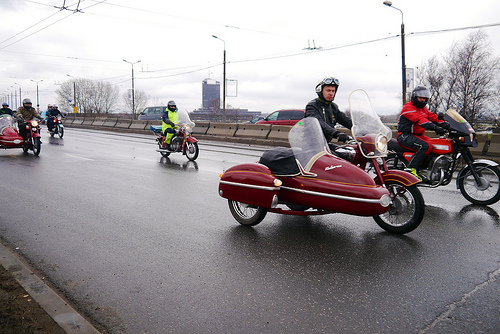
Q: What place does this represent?
A: It represents the street.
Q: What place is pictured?
A: It is a street.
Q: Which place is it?
A: It is a street.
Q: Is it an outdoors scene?
A: Yes, it is outdoors.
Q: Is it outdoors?
A: Yes, it is outdoors.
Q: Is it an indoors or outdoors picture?
A: It is outdoors.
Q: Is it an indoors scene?
A: No, it is outdoors.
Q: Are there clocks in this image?
A: No, there are no clocks.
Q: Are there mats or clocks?
A: No, there are no clocks or mats.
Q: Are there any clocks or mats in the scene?
A: No, there are no clocks or mats.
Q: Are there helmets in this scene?
A: Yes, there is a helmet.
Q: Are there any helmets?
A: Yes, there is a helmet.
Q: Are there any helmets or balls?
A: Yes, there is a helmet.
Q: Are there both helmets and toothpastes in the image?
A: No, there is a helmet but no toothpastes.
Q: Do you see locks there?
A: No, there are no locks.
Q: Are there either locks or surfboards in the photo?
A: No, there are no locks or surfboards.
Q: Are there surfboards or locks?
A: No, there are no locks or surfboards.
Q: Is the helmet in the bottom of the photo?
A: No, the helmet is in the top of the image.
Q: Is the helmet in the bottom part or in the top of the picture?
A: The helmet is in the top of the image.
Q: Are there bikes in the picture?
A: Yes, there is a bike.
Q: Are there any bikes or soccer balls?
A: Yes, there is a bike.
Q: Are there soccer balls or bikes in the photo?
A: Yes, there is a bike.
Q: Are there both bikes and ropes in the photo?
A: No, there is a bike but no ropes.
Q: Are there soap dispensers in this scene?
A: No, there are no soap dispensers.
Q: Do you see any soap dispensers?
A: No, there are no soap dispensers.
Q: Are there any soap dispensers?
A: No, there are no soap dispensers.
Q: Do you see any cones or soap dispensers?
A: No, there are no soap dispensers or cones.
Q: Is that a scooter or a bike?
A: That is a bike.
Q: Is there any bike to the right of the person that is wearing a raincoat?
A: Yes, there is a bike to the right of the person.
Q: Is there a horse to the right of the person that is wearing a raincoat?
A: No, there is a bike to the right of the person.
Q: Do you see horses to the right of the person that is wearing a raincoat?
A: No, there is a bike to the right of the person.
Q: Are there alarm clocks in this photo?
A: No, there are no alarm clocks.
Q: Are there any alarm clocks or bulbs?
A: No, there are no alarm clocks or bulbs.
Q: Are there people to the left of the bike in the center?
A: Yes, there is a person to the left of the bike.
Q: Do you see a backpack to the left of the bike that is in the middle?
A: No, there is a person to the left of the bike.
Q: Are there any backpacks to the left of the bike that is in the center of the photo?
A: No, there is a person to the left of the bike.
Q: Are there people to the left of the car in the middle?
A: Yes, there is a person to the left of the car.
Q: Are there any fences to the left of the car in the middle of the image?
A: No, there is a person to the left of the car.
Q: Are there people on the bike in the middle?
A: Yes, there is a person on the bike.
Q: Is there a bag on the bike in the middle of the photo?
A: No, there is a person on the bike.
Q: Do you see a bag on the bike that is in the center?
A: No, there is a person on the bike.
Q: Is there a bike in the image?
A: Yes, there is a bike.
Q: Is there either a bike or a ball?
A: Yes, there is a bike.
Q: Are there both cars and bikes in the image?
A: Yes, there are both a bike and a car.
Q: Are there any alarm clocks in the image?
A: No, there are no alarm clocks.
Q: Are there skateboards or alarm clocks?
A: No, there are no alarm clocks or skateboards.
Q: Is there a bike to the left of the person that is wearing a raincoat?
A: Yes, there is a bike to the left of the person.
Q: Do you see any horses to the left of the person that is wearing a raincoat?
A: No, there is a bike to the left of the person.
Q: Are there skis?
A: No, there are no skis.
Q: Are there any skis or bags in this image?
A: No, there are no skis or bags.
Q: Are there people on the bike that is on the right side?
A: Yes, there is a person on the bike.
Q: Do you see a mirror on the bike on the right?
A: No, there is a person on the bike.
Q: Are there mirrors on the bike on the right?
A: No, there is a person on the bike.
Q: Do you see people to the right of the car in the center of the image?
A: Yes, there is a person to the right of the car.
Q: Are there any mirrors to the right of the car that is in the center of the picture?
A: No, there is a person to the right of the car.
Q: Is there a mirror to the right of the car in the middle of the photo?
A: No, there is a person to the right of the car.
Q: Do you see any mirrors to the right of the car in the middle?
A: No, there is a person to the right of the car.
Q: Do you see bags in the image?
A: No, there are no bags.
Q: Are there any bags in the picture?
A: No, there are no bags.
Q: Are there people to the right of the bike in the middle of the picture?
A: Yes, there is a person to the right of the bike.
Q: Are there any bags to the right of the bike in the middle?
A: No, there is a person to the right of the bike.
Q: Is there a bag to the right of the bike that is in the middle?
A: No, there is a person to the right of the bike.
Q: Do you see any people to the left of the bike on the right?
A: Yes, there is a person to the left of the bike.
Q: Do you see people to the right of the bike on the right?
A: No, the person is to the left of the bike.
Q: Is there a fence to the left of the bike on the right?
A: No, there is a person to the left of the bike.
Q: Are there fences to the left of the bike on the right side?
A: No, there is a person to the left of the bike.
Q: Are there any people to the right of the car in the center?
A: Yes, there is a person to the right of the car.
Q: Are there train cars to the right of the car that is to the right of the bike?
A: No, there is a person to the right of the car.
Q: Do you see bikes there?
A: Yes, there are bikes.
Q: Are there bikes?
A: Yes, there are bikes.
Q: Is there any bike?
A: Yes, there are bikes.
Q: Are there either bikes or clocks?
A: Yes, there are bikes.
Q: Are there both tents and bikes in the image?
A: No, there are bikes but no tents.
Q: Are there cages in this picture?
A: No, there are no cages.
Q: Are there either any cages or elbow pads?
A: No, there are no cages or elbow pads.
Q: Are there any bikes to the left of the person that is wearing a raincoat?
A: Yes, there are bikes to the left of the person.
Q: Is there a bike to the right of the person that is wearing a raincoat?
A: No, the bikes are to the left of the person.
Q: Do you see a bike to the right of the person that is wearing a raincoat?
A: No, the bikes are to the left of the person.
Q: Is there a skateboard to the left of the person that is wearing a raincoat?
A: No, there are bikes to the left of the person.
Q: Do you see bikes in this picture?
A: Yes, there is a bike.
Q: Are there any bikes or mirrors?
A: Yes, there is a bike.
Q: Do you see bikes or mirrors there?
A: Yes, there is a bike.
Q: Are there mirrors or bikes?
A: Yes, there is a bike.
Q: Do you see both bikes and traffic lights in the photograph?
A: No, there is a bike but no traffic lights.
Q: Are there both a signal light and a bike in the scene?
A: No, there is a bike but no traffic lights.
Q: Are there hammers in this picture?
A: No, there are no hammers.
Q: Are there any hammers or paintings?
A: No, there are no hammers or paintings.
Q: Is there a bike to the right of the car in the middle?
A: Yes, there is a bike to the right of the car.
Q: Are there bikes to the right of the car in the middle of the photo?
A: Yes, there is a bike to the right of the car.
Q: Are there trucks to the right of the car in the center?
A: No, there is a bike to the right of the car.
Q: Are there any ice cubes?
A: No, there are no ice cubes.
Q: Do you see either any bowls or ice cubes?
A: No, there are no ice cubes or bowls.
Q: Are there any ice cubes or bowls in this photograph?
A: No, there are no ice cubes or bowls.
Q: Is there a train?
A: No, there are no trains.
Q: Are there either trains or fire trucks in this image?
A: No, there are no trains or fire trucks.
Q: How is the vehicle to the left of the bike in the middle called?
A: The vehicle is a car.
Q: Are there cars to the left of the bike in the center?
A: Yes, there is a car to the left of the bike.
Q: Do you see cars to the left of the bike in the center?
A: Yes, there is a car to the left of the bike.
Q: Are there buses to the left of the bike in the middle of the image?
A: No, there is a car to the left of the bike.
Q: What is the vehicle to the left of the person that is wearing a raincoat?
A: The vehicle is a car.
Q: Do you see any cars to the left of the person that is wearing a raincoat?
A: Yes, there is a car to the left of the person.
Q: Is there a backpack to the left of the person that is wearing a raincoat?
A: No, there is a car to the left of the person.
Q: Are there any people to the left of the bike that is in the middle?
A: Yes, there is a person to the left of the bike.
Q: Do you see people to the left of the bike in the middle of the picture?
A: Yes, there is a person to the left of the bike.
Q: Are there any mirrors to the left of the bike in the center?
A: No, there is a person to the left of the bike.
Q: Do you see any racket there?
A: No, there are no rackets.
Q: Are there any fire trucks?
A: No, there are no fire trucks.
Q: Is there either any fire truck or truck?
A: No, there are no fire trucks or trucks.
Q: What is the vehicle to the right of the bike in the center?
A: The vehicle is a car.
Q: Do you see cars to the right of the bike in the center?
A: Yes, there is a car to the right of the bike.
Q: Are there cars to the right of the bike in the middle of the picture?
A: Yes, there is a car to the right of the bike.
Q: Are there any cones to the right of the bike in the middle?
A: No, there is a car to the right of the bike.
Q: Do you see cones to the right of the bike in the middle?
A: No, there is a car to the right of the bike.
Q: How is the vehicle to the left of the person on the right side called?
A: The vehicle is a car.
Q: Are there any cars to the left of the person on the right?
A: Yes, there is a car to the left of the person.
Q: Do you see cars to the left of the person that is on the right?
A: Yes, there is a car to the left of the person.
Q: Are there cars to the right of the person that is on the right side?
A: No, the car is to the left of the person.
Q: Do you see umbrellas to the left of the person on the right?
A: No, there is a car to the left of the person.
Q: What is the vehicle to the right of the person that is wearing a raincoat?
A: The vehicle is a car.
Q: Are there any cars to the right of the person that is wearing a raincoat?
A: Yes, there is a car to the right of the person.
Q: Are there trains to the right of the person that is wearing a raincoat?
A: No, there is a car to the right of the person.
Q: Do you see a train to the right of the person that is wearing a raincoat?
A: No, there is a car to the right of the person.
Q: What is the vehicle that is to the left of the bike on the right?
A: The vehicle is a car.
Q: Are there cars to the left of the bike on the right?
A: Yes, there is a car to the left of the bike.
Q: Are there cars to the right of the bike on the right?
A: No, the car is to the left of the bike.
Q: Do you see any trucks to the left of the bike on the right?
A: No, there is a car to the left of the bike.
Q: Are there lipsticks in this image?
A: No, there are no lipsticks.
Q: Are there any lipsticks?
A: No, there are no lipsticks.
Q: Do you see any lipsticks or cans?
A: No, there are no lipsticks or cans.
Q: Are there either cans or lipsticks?
A: No, there are no lipsticks or cans.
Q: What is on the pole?
A: The street light is on the pole.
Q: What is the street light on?
A: The street light is on the pole.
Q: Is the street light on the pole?
A: Yes, the street light is on the pole.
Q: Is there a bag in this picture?
A: No, there are no bags.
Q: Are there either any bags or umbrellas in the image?
A: No, there are no bags or umbrellas.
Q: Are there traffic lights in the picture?
A: No, there are no traffic lights.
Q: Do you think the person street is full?
A: Yes, the street is full.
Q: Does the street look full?
A: Yes, the street is full.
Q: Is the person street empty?
A: No, the street is full.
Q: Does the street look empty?
A: No, the street is full.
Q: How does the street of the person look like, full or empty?
A: The street is full.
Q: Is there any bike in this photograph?
A: Yes, there is a bike.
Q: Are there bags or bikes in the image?
A: Yes, there is a bike.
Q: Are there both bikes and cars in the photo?
A: Yes, there are both a bike and a car.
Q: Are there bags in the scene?
A: No, there are no bags.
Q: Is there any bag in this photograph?
A: No, there are no bags.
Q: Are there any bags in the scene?
A: No, there are no bags.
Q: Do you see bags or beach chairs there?
A: No, there are no bags or beach chairs.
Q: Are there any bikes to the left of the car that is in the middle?
A: Yes, there is a bike to the left of the car.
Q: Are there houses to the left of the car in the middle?
A: No, there is a bike to the left of the car.